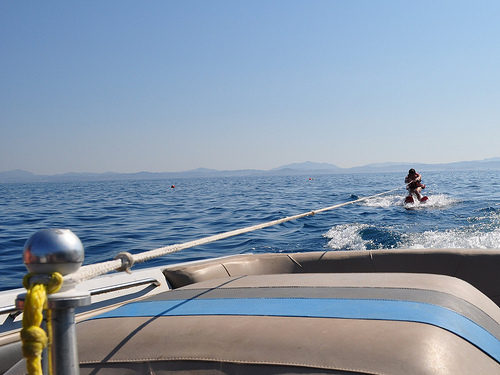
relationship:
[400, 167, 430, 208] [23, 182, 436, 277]
man holding rope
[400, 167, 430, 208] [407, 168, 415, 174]
person has hair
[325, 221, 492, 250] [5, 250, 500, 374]
white caps behind boat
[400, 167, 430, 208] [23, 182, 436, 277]
person holds rope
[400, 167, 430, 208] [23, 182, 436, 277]
skier holding rope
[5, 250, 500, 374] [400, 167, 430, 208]
boat pulling skier